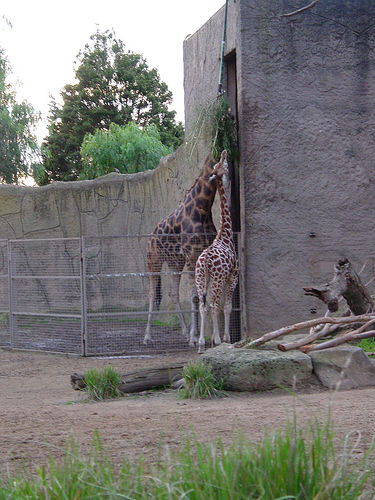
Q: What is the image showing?
A: It is showing a zoo.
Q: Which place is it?
A: It is a zoo.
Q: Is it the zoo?
A: Yes, it is the zoo.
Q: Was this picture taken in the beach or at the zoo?
A: It was taken at the zoo.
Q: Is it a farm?
A: No, it is a zoo.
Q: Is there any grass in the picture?
A: Yes, there is grass.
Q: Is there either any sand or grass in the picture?
A: Yes, there is grass.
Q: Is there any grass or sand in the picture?
A: Yes, there is grass.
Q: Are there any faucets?
A: No, there are no faucets.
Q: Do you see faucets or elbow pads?
A: No, there are no faucets or elbow pads.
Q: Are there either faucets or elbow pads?
A: No, there are no faucets or elbow pads.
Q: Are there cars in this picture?
A: No, there are no cars.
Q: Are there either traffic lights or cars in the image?
A: No, there are no cars or traffic lights.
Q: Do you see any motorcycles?
A: No, there are no motorcycles.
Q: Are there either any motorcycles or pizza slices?
A: No, there are no motorcycles or pizza slices.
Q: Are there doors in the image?
A: Yes, there is a door.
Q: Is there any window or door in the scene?
A: Yes, there is a door.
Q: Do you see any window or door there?
A: Yes, there is a door.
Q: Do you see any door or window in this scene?
A: Yes, there is a door.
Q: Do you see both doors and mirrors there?
A: No, there is a door but no mirrors.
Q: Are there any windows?
A: No, there are no windows.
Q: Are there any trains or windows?
A: No, there are no windows or trains.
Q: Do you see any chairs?
A: No, there are no chairs.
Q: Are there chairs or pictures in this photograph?
A: No, there are no chairs or pictures.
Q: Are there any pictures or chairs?
A: No, there are no chairs or pictures.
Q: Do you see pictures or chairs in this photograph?
A: No, there are no chairs or pictures.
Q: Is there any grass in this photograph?
A: Yes, there is grass.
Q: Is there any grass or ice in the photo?
A: Yes, there is grass.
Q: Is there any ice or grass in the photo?
A: Yes, there is grass.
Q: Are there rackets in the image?
A: No, there are no rackets.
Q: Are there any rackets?
A: No, there are no rackets.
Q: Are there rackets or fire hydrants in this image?
A: No, there are no rackets or fire hydrants.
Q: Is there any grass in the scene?
A: Yes, there is grass.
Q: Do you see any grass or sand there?
A: Yes, there is grass.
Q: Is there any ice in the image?
A: No, there is no ice.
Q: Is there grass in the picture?
A: Yes, there is grass.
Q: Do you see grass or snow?
A: Yes, there is grass.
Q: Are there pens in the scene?
A: No, there are no pens.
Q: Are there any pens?
A: No, there are no pens.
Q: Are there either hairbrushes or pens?
A: No, there are no pens or hairbrushes.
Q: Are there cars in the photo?
A: No, there are no cars.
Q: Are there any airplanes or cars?
A: No, there are no cars or airplanes.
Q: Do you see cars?
A: No, there are no cars.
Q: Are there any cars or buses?
A: No, there are no cars or buses.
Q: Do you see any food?
A: Yes, there is food.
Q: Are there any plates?
A: No, there are no plates.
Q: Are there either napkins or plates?
A: No, there are no plates or napkins.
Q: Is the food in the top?
A: Yes, the food is in the top of the image.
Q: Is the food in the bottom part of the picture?
A: No, the food is in the top of the image.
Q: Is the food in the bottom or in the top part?
A: The food is in the top of the image.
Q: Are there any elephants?
A: No, there are no elephants.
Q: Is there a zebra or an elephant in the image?
A: No, there are no elephants or zebras.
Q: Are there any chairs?
A: No, there are no chairs.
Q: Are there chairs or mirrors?
A: No, there are no chairs or mirrors.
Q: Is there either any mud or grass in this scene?
A: Yes, there is grass.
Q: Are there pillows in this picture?
A: No, there are no pillows.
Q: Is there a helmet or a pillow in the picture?
A: No, there are no pillows or helmets.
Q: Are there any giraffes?
A: Yes, there is a giraffe.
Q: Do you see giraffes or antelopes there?
A: Yes, there is a giraffe.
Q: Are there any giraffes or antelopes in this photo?
A: Yes, there is a giraffe.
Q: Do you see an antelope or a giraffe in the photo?
A: Yes, there is a giraffe.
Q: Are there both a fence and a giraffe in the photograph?
A: Yes, there are both a giraffe and a fence.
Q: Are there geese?
A: No, there are no geese.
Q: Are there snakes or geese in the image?
A: No, there are no geese or snakes.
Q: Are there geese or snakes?
A: No, there are no geese or snakes.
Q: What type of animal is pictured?
A: The animal is a giraffe.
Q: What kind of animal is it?
A: The animal is a giraffe.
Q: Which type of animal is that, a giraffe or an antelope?
A: That is a giraffe.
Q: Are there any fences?
A: Yes, there is a fence.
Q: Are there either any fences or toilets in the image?
A: Yes, there is a fence.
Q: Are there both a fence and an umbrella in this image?
A: No, there is a fence but no umbrellas.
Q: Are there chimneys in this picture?
A: No, there are no chimneys.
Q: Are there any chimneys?
A: No, there are no chimneys.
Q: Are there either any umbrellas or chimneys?
A: No, there are no chimneys or umbrellas.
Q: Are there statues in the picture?
A: No, there are no statues.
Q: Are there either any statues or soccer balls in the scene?
A: No, there are no statues or soccer balls.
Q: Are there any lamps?
A: No, there are no lamps.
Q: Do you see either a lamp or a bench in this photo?
A: No, there are no lamps or benches.